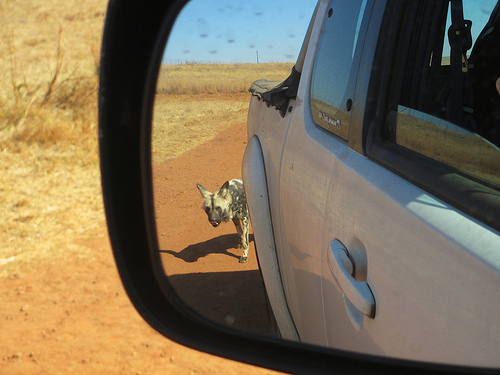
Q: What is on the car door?
A: Big window.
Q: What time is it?
A: Afternoon.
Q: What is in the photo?
A: Mirror.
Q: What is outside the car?
A: Animal.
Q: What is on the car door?
A: Handle.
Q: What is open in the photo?
A: Car window.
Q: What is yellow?
A: Grass.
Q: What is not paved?
A: The road.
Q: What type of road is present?
A: An orange dirt road.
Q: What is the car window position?
A: Down.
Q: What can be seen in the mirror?
A: A hyena.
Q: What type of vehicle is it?
A: A truck.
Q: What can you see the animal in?
A: The side mirror reflection.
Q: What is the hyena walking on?
A: An orange dirt road.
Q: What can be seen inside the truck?
A: The seatbelt.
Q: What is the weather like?
A: Bright blue skies.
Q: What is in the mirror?
A: A coyote.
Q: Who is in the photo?
A: Nobody.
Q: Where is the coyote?
A: Behind the truck.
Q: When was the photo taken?
A: Daytime.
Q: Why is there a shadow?
A: It is sunny.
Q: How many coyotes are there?
A: One.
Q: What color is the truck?
A: White.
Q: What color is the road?
A: Brown.